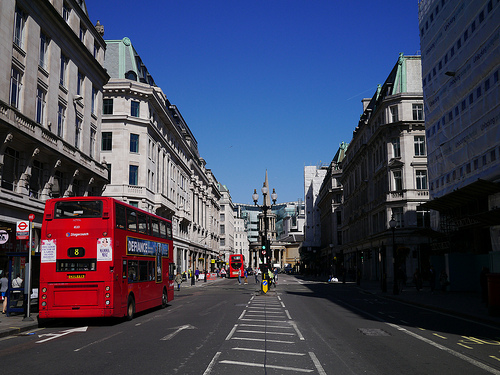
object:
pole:
[259, 189, 270, 266]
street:
[0, 265, 499, 374]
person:
[174, 270, 182, 290]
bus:
[228, 252, 245, 278]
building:
[312, 140, 343, 272]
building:
[338, 52, 445, 292]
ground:
[0, 264, 499, 374]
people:
[186, 253, 227, 284]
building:
[414, 0, 500, 327]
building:
[324, 140, 347, 285]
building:
[232, 212, 254, 274]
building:
[1, 0, 109, 321]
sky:
[82, 0, 419, 205]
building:
[81, 36, 223, 296]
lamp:
[251, 165, 278, 263]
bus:
[38, 195, 174, 321]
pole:
[27, 214, 37, 324]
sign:
[16, 221, 27, 234]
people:
[236, 262, 284, 298]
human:
[2, 271, 23, 316]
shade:
[288, 254, 498, 343]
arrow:
[155, 319, 200, 340]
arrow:
[34, 324, 95, 342]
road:
[0, 261, 499, 375]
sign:
[216, 265, 226, 279]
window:
[128, 134, 140, 154]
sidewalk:
[0, 260, 222, 331]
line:
[306, 349, 337, 374]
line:
[200, 350, 220, 374]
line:
[73, 327, 120, 352]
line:
[445, 345, 500, 373]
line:
[280, 308, 294, 320]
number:
[72, 246, 80, 257]